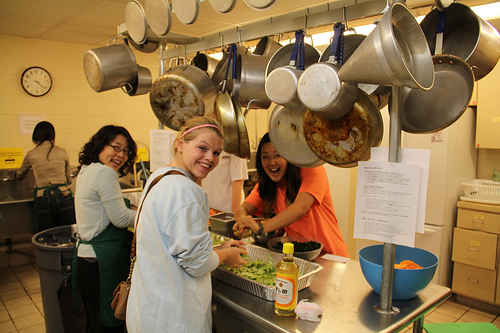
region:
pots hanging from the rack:
[79, 1, 498, 169]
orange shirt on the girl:
[241, 163, 351, 257]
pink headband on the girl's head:
[173, 120, 224, 139]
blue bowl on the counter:
[357, 243, 440, 295]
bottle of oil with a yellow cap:
[271, 238, 301, 316]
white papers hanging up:
[353, 143, 429, 250]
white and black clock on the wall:
[18, 65, 54, 98]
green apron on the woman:
[68, 222, 133, 331]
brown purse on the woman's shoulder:
[106, 165, 187, 322]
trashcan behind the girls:
[29, 224, 129, 330]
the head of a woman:
[157, 123, 238, 184]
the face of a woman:
[163, 133, 231, 186]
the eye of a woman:
[190, 115, 230, 157]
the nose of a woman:
[193, 146, 223, 164]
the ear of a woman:
[172, 130, 212, 170]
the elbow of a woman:
[162, 240, 234, 292]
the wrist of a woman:
[205, 237, 240, 269]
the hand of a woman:
[219, 215, 276, 267]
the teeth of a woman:
[179, 158, 227, 185]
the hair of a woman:
[149, 99, 251, 186]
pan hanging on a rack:
[356, 4, 438, 111]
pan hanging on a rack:
[294, 59, 356, 117]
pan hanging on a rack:
[264, 60, 296, 102]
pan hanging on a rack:
[232, 47, 273, 99]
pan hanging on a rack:
[215, 87, 242, 130]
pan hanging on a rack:
[157, 67, 209, 118]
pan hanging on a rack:
[92, 30, 148, 87]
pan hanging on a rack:
[208, 92, 243, 167]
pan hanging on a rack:
[427, 24, 481, 90]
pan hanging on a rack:
[305, 112, 373, 166]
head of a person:
[159, 94, 244, 195]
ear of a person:
[166, 134, 186, 156]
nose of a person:
[198, 150, 219, 164]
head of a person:
[254, 132, 294, 184]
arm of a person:
[262, 182, 309, 236]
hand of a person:
[222, 210, 263, 244]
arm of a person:
[175, 245, 220, 285]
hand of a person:
[220, 232, 252, 267]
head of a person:
[91, 112, 148, 182]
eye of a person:
[108, 142, 136, 153]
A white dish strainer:
[461, 173, 498, 204]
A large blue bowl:
[352, 238, 435, 303]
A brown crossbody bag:
[96, 167, 189, 323]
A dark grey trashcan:
[31, 218, 86, 331]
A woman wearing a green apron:
[62, 110, 138, 330]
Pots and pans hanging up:
[76, 2, 497, 168]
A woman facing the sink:
[2, 125, 92, 245]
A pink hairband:
[175, 106, 221, 146]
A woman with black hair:
[60, 120, 146, 327]